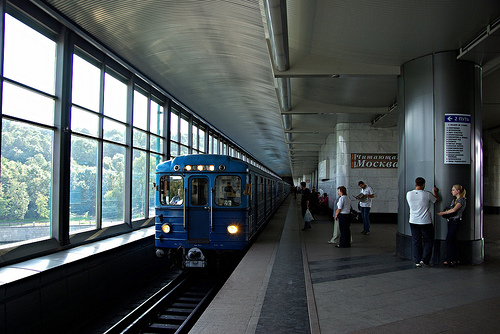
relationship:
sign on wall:
[350, 152, 398, 169] [332, 110, 404, 231]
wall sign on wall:
[443, 114, 471, 165] [329, 105, 461, 253]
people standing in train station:
[333, 185, 352, 248] [3, 1, 474, 331]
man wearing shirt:
[388, 175, 468, 280] [404, 190, 433, 226]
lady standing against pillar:
[438, 184, 475, 259] [423, 62, 495, 254]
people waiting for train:
[333, 185, 352, 248] [131, 142, 288, 257]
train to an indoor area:
[154, 154, 293, 272] [2, 1, 497, 332]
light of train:
[228, 222, 241, 234] [154, 154, 293, 272]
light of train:
[159, 221, 170, 232] [154, 154, 293, 272]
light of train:
[207, 165, 214, 172] [154, 154, 293, 272]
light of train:
[195, 162, 203, 169] [154, 154, 293, 272]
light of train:
[183, 162, 191, 170] [154, 154, 293, 272]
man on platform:
[404, 176, 440, 268] [189, 190, 499, 332]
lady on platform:
[436, 184, 467, 266] [189, 190, 499, 332]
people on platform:
[332, 184, 352, 248] [189, 190, 499, 332]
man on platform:
[351, 180, 376, 235] [189, 190, 499, 332]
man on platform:
[298, 181, 313, 231] [189, 190, 499, 332]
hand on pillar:
[431, 182, 441, 197] [403, 60, 477, 268]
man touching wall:
[404, 176, 440, 268] [335, 118, 400, 220]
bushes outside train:
[3, 119, 225, 218] [154, 154, 293, 272]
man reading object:
[343, 169, 379, 241] [350, 192, 366, 201]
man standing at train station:
[294, 178, 316, 228] [3, 1, 474, 331]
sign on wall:
[341, 142, 418, 178] [342, 123, 401, 213]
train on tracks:
[121, 100, 303, 275] [44, 276, 226, 332]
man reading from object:
[351, 180, 376, 235] [348, 190, 368, 203]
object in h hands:
[348, 190, 368, 203] [346, 187, 369, 201]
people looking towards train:
[333, 185, 352, 248] [151, 140, 283, 249]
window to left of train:
[63, 56, 102, 228] [152, 135, 292, 277]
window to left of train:
[103, 72, 130, 222] [152, 135, 292, 277]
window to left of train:
[128, 93, 149, 233] [152, 135, 292, 277]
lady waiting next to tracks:
[436, 184, 467, 266] [103, 246, 243, 330]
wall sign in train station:
[442, 111, 472, 166] [0, 0, 498, 333]